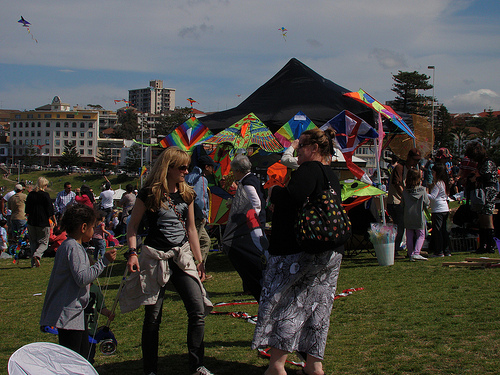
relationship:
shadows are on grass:
[43, 170, 145, 185] [2, 163, 499, 372]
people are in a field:
[2, 124, 500, 373] [2, 163, 499, 372]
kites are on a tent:
[15, 8, 294, 114] [179, 57, 401, 131]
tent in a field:
[179, 57, 401, 131] [2, 163, 499, 372]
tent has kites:
[179, 57, 401, 131] [15, 8, 294, 114]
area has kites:
[1, 1, 499, 374] [15, 8, 294, 114]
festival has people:
[3, 56, 500, 374] [2, 124, 500, 373]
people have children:
[2, 124, 500, 373] [400, 161, 455, 263]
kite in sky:
[15, 13, 46, 45] [0, 0, 496, 119]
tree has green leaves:
[386, 69, 431, 155] [382, 69, 436, 116]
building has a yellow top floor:
[10, 110, 133, 165] [8, 109, 103, 121]